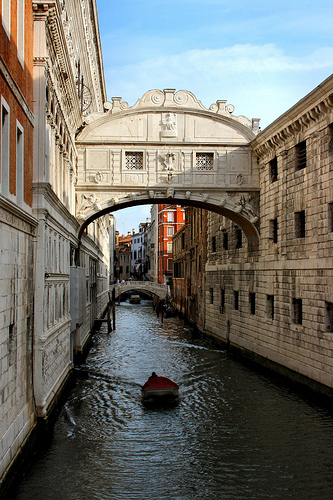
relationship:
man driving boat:
[147, 369, 156, 376] [142, 374, 179, 402]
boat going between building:
[136, 370, 182, 407] [244, 72, 332, 391]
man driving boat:
[148, 372, 158, 380] [142, 377, 181, 396]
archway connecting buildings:
[71, 89, 263, 249] [201, 66, 332, 379]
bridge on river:
[76, 85, 262, 249] [5, 297, 331, 498]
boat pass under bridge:
[121, 293, 161, 312] [100, 267, 199, 304]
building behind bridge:
[149, 203, 181, 302] [46, 79, 285, 242]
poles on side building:
[96, 284, 120, 332] [165, 80, 331, 388]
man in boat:
[148, 372, 158, 380] [138, 376, 180, 411]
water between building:
[110, 312, 161, 349] [73, 107, 293, 308]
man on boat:
[148, 372, 158, 380] [140, 375, 179, 406]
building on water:
[0, 0, 333, 500] [0, 254, 332, 499]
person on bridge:
[112, 266, 121, 286] [117, 278, 162, 311]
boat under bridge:
[129, 295, 141, 303] [108, 280, 169, 304]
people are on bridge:
[116, 277, 125, 283] [108, 279, 169, 302]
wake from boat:
[78, 359, 225, 392] [140, 372, 184, 402]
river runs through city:
[1, 1, 331, 497] [1, 1, 330, 497]